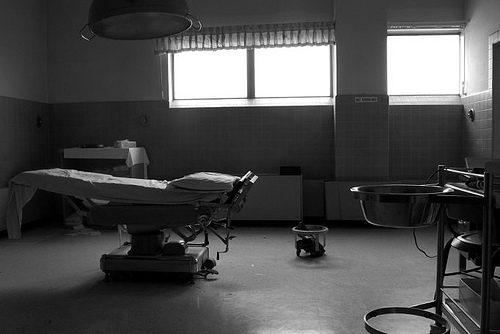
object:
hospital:
[111, 42, 428, 296]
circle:
[99, 5, 204, 42]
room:
[14, 46, 486, 321]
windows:
[171, 39, 242, 109]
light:
[105, 3, 126, 11]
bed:
[23, 162, 223, 210]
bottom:
[111, 206, 159, 233]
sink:
[348, 182, 422, 226]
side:
[36, 78, 77, 116]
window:
[258, 51, 324, 89]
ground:
[274, 289, 319, 313]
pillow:
[191, 169, 230, 182]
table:
[115, 177, 155, 187]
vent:
[287, 169, 303, 177]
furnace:
[94, 41, 96, 44]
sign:
[356, 93, 382, 105]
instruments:
[445, 164, 467, 188]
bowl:
[92, 136, 127, 151]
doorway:
[471, 25, 497, 44]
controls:
[167, 220, 220, 236]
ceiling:
[8, 1, 41, 22]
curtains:
[239, 28, 274, 49]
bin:
[280, 225, 333, 255]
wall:
[46, 19, 67, 29]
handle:
[69, 17, 95, 45]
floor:
[26, 247, 64, 268]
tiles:
[340, 12, 373, 24]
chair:
[226, 181, 247, 216]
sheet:
[87, 170, 138, 187]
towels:
[65, 212, 94, 227]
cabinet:
[128, 150, 143, 167]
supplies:
[154, 165, 203, 188]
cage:
[442, 274, 479, 313]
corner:
[445, 208, 459, 221]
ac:
[22, 106, 48, 125]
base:
[140, 231, 170, 275]